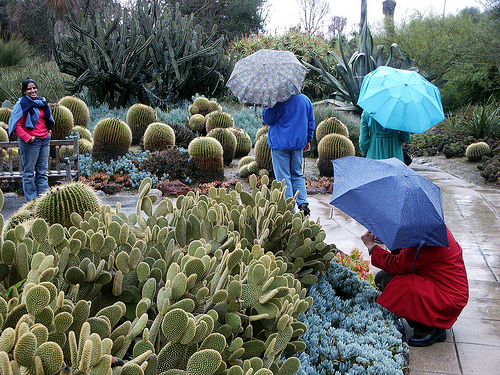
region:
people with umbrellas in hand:
[213, 37, 478, 334]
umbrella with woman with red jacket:
[323, 153, 445, 250]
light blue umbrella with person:
[350, 59, 443, 131]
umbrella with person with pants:
[227, 48, 316, 100]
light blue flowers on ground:
[308, 256, 407, 371]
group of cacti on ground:
[3, 187, 292, 367]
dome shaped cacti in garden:
[63, 95, 358, 175]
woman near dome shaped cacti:
[5, 65, 71, 198]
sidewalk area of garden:
[447, 180, 499, 369]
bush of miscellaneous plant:
[38, 9, 225, 87]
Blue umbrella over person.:
[322, 147, 447, 248]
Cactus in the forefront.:
[2, 183, 329, 373]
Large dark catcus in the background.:
[50, 5, 230, 111]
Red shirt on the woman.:
[7, 75, 57, 202]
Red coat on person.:
[355, 205, 469, 337]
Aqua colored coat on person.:
[356, 109, 413, 162]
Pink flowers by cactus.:
[332, 240, 377, 288]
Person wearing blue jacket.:
[259, 85, 321, 208]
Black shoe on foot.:
[406, 316, 448, 351]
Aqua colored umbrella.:
[357, 60, 448, 136]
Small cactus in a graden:
[463, 134, 495, 181]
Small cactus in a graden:
[312, 133, 352, 174]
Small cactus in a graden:
[315, 112, 354, 134]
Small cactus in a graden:
[184, 129, 228, 176]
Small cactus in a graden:
[140, 118, 172, 158]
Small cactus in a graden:
[82, 99, 127, 166]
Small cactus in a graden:
[120, 84, 156, 143]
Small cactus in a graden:
[181, 86, 214, 135]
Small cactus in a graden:
[194, 243, 304, 372]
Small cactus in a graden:
[87, 239, 204, 346]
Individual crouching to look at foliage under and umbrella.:
[320, 154, 469, 346]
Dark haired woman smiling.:
[6, 77, 51, 208]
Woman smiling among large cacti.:
[14, 77, 56, 199]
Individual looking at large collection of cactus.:
[228, 43, 316, 221]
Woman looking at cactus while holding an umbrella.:
[355, 67, 443, 159]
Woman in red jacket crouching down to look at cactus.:
[328, 155, 469, 349]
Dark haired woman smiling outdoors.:
[10, 77, 55, 205]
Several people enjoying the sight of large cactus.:
[226, 44, 469, 349]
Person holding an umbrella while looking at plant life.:
[225, 44, 312, 215]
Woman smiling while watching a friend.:
[9, 76, 55, 208]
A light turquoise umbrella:
[352, 56, 450, 136]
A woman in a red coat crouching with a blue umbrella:
[322, 147, 473, 349]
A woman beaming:
[6, 77, 59, 206]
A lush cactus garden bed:
[0, 169, 409, 374]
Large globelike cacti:
[1, 86, 354, 184]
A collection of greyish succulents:
[292, 254, 409, 373]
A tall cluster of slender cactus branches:
[42, 1, 236, 107]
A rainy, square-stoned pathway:
[270, 147, 496, 374]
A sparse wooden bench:
[2, 136, 89, 198]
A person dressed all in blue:
[225, 37, 316, 218]